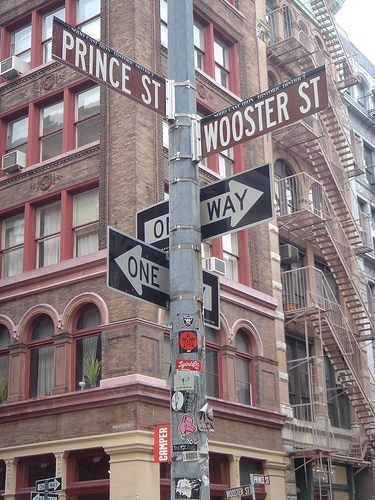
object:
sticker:
[178, 329, 197, 352]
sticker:
[174, 360, 200, 374]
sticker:
[182, 315, 194, 326]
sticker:
[173, 444, 197, 450]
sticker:
[171, 390, 186, 412]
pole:
[165, 0, 211, 500]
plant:
[84, 354, 103, 390]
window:
[28, 309, 54, 399]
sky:
[328, 0, 374, 61]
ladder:
[264, 0, 374, 462]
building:
[0, 0, 375, 499]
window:
[3, 112, 29, 169]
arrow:
[144, 178, 265, 246]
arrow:
[113, 245, 213, 314]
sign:
[50, 14, 166, 117]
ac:
[1, 148, 26, 174]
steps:
[273, 171, 374, 343]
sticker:
[173, 368, 194, 391]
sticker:
[177, 414, 196, 446]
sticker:
[174, 477, 199, 500]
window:
[71, 302, 102, 392]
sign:
[197, 64, 328, 158]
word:
[157, 426, 168, 464]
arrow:
[36, 478, 63, 498]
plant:
[42, 387, 51, 397]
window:
[33, 191, 59, 269]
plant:
[0, 376, 8, 404]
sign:
[132, 160, 275, 250]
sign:
[103, 223, 221, 333]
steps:
[280, 266, 375, 468]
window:
[32, 91, 67, 164]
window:
[65, 82, 100, 143]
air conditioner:
[0, 55, 31, 81]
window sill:
[72, 377, 99, 390]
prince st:
[59, 31, 162, 112]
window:
[71, 178, 100, 259]